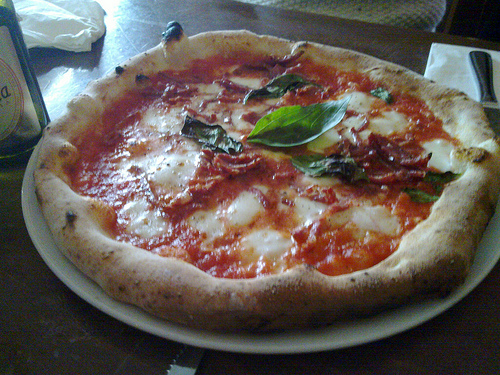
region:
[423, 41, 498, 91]
corner of white napkin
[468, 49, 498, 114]
handle of silver utensil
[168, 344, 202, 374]
serrated blade of knife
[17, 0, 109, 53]
crumpled white napkin on table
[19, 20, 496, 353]
pizza on white plate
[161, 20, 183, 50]
burn on pizza dough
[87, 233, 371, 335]
thick crust of pizza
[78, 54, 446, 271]
tomato sauce on pizza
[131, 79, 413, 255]
melted cheese on tomato sauce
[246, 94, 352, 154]
green leaf on pizza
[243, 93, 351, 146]
A green leaf in the middle of a pizza.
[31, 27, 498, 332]
A round brown pizza with toppings.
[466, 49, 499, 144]
A silver utensil to the right of a pizza.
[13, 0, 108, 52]
A white napkin that is ruffled up behind the pizza on the left.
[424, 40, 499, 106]
A white napkin on the right.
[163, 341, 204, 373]
The blade of a knife coming out from under a plate.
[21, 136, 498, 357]
The white plate a pizza is on.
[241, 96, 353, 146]
A green leaf on a pizza.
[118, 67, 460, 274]
Melted white mozzerella cheese all over a pizza.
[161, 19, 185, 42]
The largest two burnt spots on a pizza crust.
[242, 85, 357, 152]
The leaf is on the pizza.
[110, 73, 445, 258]
Cheese is on the pizza.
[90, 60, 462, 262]
Sauce is on the pizza.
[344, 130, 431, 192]
Red peppers are on the pizza.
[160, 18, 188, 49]
Burnt spot on the crust.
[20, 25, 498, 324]
The pizza is on the plate.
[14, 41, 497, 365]
The plate is white.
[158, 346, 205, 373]
The knife is under the plate.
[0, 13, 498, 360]
The plate is on the table.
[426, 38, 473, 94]
The napkin is white.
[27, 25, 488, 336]
small delicious pizza pie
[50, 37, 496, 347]
personal pizza on a white plate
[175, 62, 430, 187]
basil baked into pizza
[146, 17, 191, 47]
elevated burnt crust piece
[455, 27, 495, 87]
silver knife on table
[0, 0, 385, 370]
a brown wooden table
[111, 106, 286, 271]
mozzarella melted into pizza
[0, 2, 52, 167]
restaurant menu on table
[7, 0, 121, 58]
extra white napkin on table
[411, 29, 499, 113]
white napkin under silver knife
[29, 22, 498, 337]
whole pizza on plate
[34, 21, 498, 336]
cheese pizza on plate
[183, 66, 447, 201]
basil sprinkled on top of pizza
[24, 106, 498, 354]
white plate containing pizza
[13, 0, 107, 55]
crumpled napkin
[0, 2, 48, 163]
part of bottle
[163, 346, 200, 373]
part of silver knife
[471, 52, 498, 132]
silver knife on napkin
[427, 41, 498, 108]
white napkin under knife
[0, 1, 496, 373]
brown wooden table